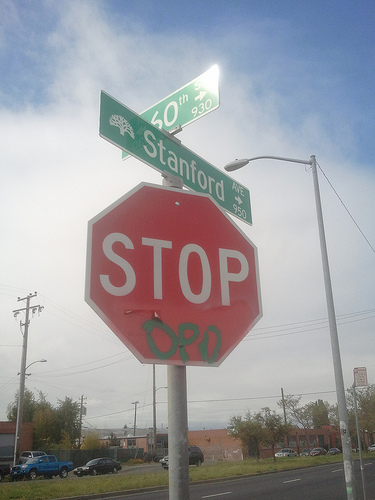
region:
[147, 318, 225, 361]
tagging on the stop sign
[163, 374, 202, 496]
a metal pole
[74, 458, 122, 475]
a black pole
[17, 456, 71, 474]
a blue truck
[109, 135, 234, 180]
a green street sign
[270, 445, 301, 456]
a car on the street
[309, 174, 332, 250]
a metal pole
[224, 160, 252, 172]
a street light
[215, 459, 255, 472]
the grass in the median of the street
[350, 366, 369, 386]
a street sign that is red and white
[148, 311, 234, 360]
graffiti on stop sign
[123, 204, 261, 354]
street sign is red and white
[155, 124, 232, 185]
Stanford Ave written on street sign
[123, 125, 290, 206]
street sign is green and white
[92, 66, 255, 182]
two street signs on top of stop sign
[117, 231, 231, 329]
STOP written in white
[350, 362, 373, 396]
street sign is red and white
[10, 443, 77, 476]
blue truck parked on the street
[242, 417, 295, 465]
trees in the median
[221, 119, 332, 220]
street light over the STOP sign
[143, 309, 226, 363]
Green graffiti on red traffic sign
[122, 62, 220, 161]
Green street sign above green street sign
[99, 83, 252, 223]
Green street sign above red traffic sign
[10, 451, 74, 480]
Blue truck parked in front of black car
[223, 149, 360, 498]
Tall light post by red traffic sign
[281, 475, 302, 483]
White traffic line on road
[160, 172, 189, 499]
Metal pole holding traffic sign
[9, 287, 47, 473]
Tall electricity post next to blue car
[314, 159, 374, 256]
Cable attached to tall light post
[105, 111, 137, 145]
White tree design on green street sign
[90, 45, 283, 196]
two green and white street signs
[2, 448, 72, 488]
a king cab blue truck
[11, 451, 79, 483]
a blue truck parked on a side of road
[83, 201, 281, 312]
a red and white stop sign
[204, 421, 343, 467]
a red brick building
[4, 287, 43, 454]
a wood electrical pole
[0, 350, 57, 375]
a street light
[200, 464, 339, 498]
white lines painted on a road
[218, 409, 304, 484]
two trees growing in the medium of a roadway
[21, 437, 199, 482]
three cars parked next to a road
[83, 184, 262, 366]
a red stop sign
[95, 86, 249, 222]
a green and white street name sign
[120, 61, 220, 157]
a green and white street name sign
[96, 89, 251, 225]
Sanford Ave street sign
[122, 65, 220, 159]
60th Street sign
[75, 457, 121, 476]
a parked black car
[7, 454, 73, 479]
a parked blue truck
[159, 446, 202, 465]
a parked black truck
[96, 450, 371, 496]
a grey paved street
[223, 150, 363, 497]
an overhead street light